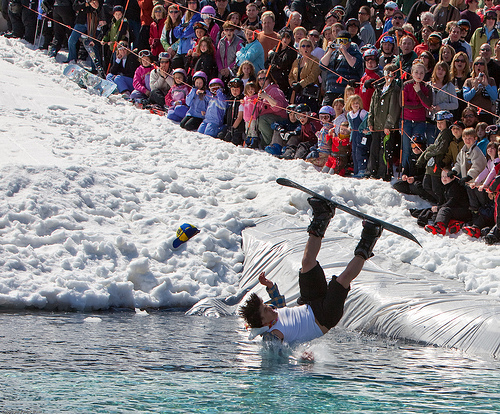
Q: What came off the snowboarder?
A: His hat.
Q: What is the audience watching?
A: A falling snowboarder.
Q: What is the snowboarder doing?
A: Landing in the water.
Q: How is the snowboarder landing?
A: Upside down.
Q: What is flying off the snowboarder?
A: Their hat.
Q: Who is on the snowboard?
A: A man.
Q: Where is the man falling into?
A: The water.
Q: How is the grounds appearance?
A: Snow.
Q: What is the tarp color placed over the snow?
A: White.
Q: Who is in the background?
A: A crowd.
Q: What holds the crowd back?
A: An orange rope.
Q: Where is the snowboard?
A: In the air.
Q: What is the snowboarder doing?
A: Falling into the water.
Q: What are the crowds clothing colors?
A: Red, white, blue and black.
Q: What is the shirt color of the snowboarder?
A: White.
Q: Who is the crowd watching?
A: A snowboarder.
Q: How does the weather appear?
A: Cold.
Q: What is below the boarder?
A: A body of water.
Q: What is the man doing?
A: Falling in the water.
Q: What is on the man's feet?
A: Snowboard.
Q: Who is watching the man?
A: Spectators.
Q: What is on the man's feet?
A: Boots.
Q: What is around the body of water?
A: Snow.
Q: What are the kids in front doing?
A: Grabbing on the rope.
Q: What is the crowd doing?
A: Watching the snowboarder.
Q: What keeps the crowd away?
A: The rope fence.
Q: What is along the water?
A: Plastic.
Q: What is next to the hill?
A: A large crowd.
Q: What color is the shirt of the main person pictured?
A: White.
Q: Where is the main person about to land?
A: Water.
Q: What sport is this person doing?
A: Snowboarding.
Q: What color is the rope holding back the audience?
A: Orange.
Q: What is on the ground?
A: Snow.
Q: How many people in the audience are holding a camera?
A: 2.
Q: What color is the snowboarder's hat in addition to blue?
A: Yellow.